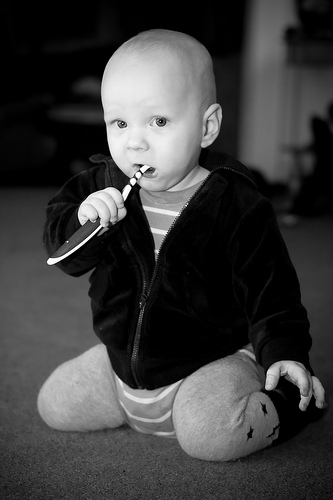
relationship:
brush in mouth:
[28, 159, 158, 262] [121, 141, 169, 181]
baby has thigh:
[35, 27, 327, 462] [189, 360, 273, 412]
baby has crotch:
[35, 27, 327, 462] [111, 380, 185, 441]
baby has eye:
[35, 27, 327, 462] [151, 110, 174, 132]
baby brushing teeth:
[35, 27, 327, 462] [148, 166, 155, 171]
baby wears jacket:
[35, 27, 327, 462] [43, 154, 312, 389]